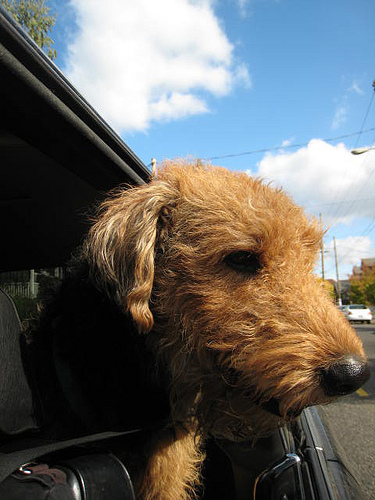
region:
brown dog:
[81, 152, 371, 448]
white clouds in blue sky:
[131, 25, 186, 57]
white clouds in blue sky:
[266, 23, 362, 96]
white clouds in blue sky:
[190, 50, 232, 83]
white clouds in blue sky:
[272, 91, 325, 141]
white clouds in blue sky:
[188, 72, 251, 107]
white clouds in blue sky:
[268, 68, 320, 116]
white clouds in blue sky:
[218, 67, 256, 95]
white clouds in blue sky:
[182, 27, 248, 88]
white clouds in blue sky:
[296, 56, 343, 102]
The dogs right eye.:
[213, 243, 262, 289]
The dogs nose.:
[318, 354, 372, 406]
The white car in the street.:
[339, 300, 371, 322]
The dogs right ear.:
[92, 178, 173, 329]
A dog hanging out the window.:
[75, 157, 372, 499]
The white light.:
[351, 138, 374, 168]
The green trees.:
[8, 3, 58, 39]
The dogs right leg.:
[139, 408, 202, 495]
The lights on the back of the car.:
[347, 309, 371, 314]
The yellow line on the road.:
[356, 386, 369, 399]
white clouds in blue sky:
[147, 48, 209, 94]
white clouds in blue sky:
[280, 38, 330, 93]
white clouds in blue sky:
[312, 71, 363, 153]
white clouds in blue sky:
[286, 147, 343, 192]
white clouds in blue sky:
[107, 68, 155, 98]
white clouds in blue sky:
[204, 7, 234, 60]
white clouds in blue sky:
[128, 14, 201, 84]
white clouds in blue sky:
[243, 104, 290, 143]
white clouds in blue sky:
[273, 0, 346, 58]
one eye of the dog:
[225, 244, 265, 274]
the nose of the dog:
[320, 355, 367, 395]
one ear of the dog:
[86, 182, 170, 329]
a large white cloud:
[69, 3, 244, 91]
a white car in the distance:
[343, 304, 373, 320]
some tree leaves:
[4, 0, 58, 58]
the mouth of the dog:
[252, 381, 307, 420]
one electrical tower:
[330, 237, 344, 300]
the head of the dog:
[90, 158, 363, 404]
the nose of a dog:
[320, 357, 365, 396]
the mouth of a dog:
[256, 388, 304, 421]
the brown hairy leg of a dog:
[140, 400, 207, 498]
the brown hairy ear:
[85, 179, 175, 327]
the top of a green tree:
[3, 0, 60, 61]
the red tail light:
[346, 308, 352, 316]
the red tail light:
[366, 311, 371, 317]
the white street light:
[349, 142, 372, 159]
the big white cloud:
[62, 4, 240, 132]